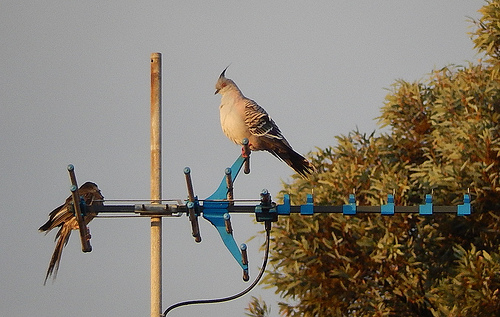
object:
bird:
[215, 66, 315, 183]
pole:
[149, 50, 163, 316]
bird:
[39, 181, 104, 285]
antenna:
[69, 138, 474, 282]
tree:
[242, 0, 499, 317]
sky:
[0, 1, 490, 317]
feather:
[220, 63, 231, 77]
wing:
[245, 98, 280, 140]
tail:
[274, 130, 315, 180]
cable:
[163, 222, 273, 317]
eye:
[222, 82, 226, 87]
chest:
[221, 92, 240, 129]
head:
[83, 182, 101, 195]